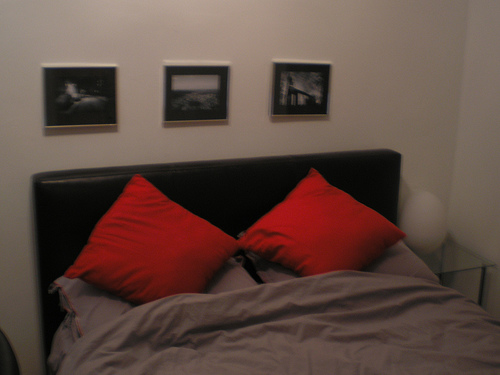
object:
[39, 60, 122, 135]
frame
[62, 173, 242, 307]
pillow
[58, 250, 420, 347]
sheet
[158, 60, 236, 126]
picture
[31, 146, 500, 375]
bed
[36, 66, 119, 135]
photo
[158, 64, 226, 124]
black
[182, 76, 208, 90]
white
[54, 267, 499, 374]
comforter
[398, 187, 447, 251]
light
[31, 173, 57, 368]
post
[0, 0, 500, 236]
wall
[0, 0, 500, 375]
bathroom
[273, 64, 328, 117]
photograph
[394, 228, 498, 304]
table